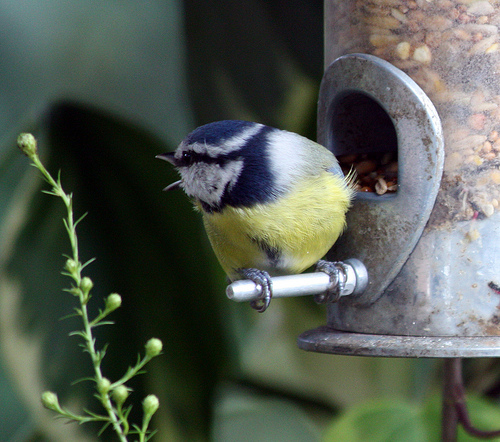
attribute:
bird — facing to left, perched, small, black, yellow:
[149, 120, 361, 312]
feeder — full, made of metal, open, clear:
[295, 1, 499, 440]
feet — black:
[239, 260, 349, 311]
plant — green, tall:
[14, 128, 165, 429]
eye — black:
[178, 147, 194, 163]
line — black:
[190, 148, 242, 165]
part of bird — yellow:
[186, 159, 361, 283]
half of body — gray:
[177, 120, 336, 203]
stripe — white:
[188, 119, 263, 157]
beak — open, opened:
[153, 151, 180, 192]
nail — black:
[316, 259, 337, 291]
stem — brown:
[30, 152, 133, 441]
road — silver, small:
[225, 254, 369, 306]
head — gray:
[169, 123, 264, 199]